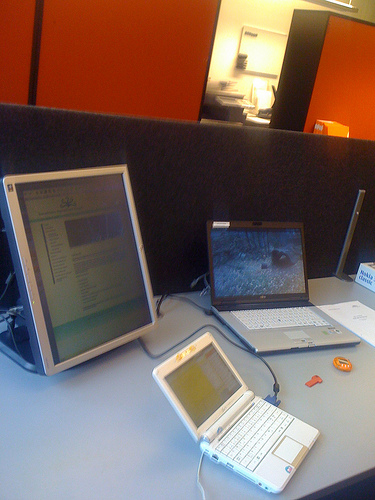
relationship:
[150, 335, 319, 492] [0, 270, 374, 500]
computer on table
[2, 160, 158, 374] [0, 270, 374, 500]
computer on table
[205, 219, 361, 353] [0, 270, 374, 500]
computer on table